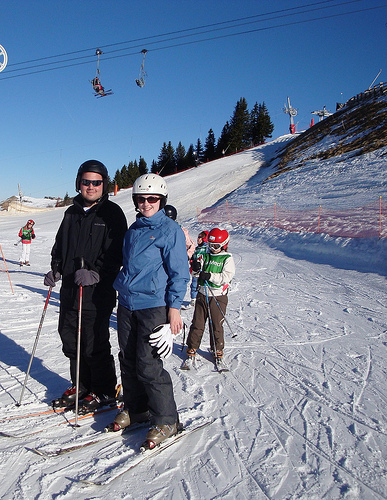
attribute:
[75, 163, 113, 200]
helmet — black, white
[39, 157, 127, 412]
man — adult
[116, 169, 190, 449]
woman — adult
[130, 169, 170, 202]
helmet — white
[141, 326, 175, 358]
glove — black, white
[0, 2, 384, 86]
wires — hanging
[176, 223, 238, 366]
child — skiing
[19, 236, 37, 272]
pants — white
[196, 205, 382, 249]
fence — orange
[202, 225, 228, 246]
helmet — red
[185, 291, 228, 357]
pants — brown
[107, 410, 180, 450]
boots — brown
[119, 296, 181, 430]
pants — black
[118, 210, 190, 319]
jacket — blue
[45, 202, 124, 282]
jacket — black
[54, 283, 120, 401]
pants — black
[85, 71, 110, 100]
ski lift chair — empty